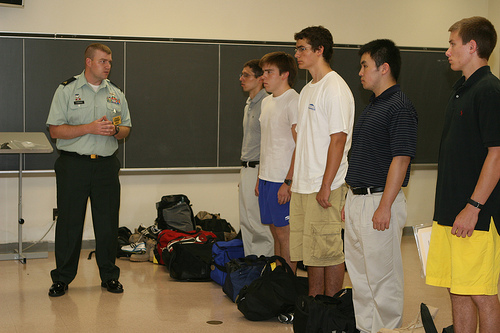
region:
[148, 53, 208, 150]
a portion of the chalkboard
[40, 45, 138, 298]
a military officer standing by chalkboard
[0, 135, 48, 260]
a movable podium for speaking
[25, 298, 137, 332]
part of the brown floor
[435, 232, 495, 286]
a part of the man's yellow shorts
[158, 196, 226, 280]
a pile of various duffle bags on floor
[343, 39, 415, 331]
a timid recruit standing at attention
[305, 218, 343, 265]
a pocket on the man's brown shorts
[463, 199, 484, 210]
a black ban on man's wrist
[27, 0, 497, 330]
five young men standing by military officer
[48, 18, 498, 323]
There are six men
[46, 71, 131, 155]
The shirt is green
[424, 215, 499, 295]
The shorts are yellow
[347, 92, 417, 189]
The shirt has stripes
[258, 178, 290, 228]
The shorts are blue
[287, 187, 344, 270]
The shorts are khaki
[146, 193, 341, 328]
There are many bags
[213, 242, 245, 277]
One bag is blue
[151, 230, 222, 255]
One bag is red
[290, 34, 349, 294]
The man has glasses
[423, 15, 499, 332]
The young man is wearing yellow shorts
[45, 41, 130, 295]
The man is wearing a uniform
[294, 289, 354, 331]
A black duffel bag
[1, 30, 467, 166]
A long chalk board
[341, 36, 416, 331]
The person is wearing a belt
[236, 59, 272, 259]
The young man is wearing glasses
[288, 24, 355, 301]
The guy is wearing a white shirt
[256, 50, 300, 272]
This person is wearing blue short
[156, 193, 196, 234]
Black and grey duffel bag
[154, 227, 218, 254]
The top of a red duffel bag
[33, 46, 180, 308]
Police officer in the room.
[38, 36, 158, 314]
Man in an officer's uniform.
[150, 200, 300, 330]
Bags on the ground.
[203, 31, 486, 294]
People standing in front of the officer.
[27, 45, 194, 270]
Police officer.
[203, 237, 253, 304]
Blue bag on the ground.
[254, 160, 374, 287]
Boy in khaki shorts.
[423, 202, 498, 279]
Boy in yellow shorts.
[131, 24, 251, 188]
Blackboard on the wall.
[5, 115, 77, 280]
Table on the ground.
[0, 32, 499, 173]
the black board on the wall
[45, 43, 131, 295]
the man standing in front of the line of young man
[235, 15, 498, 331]
the young men standing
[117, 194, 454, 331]
the bags on the ground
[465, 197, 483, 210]
the watch on the young man's arm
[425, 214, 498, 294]
the yellow shorts on the young man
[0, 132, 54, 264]
the podium next to the black board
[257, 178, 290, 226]
the blue shorts on the young man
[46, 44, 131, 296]
the man dressed in a military uniform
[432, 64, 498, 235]
the black short sleeved shirt on the young man